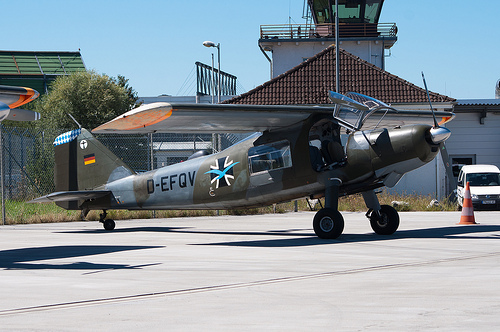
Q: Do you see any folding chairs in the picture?
A: No, there are no folding chairs.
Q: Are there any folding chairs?
A: No, there are no folding chairs.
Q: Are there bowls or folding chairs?
A: No, there are no folding chairs or bowls.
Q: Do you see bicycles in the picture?
A: No, there are no bicycles.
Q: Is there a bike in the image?
A: No, there are no bikes.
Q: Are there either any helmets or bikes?
A: No, there are no bikes or helmets.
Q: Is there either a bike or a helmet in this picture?
A: No, there are no bikes or helmets.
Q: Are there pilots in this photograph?
A: No, there are no pilots.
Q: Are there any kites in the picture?
A: No, there are no kites.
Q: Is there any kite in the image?
A: No, there are no kites.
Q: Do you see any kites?
A: No, there are no kites.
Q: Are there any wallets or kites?
A: No, there are no kites or wallets.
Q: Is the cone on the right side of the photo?
A: Yes, the cone is on the right of the image.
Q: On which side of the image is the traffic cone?
A: The traffic cone is on the right of the image.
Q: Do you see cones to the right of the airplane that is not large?
A: Yes, there is a cone to the right of the airplane.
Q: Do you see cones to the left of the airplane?
A: No, the cone is to the right of the airplane.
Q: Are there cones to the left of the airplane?
A: No, the cone is to the right of the airplane.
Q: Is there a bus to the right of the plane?
A: No, there is a cone to the right of the plane.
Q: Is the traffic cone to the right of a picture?
A: No, the traffic cone is to the right of the airplane.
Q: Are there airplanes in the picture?
A: Yes, there is an airplane.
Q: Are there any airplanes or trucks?
A: Yes, there is an airplane.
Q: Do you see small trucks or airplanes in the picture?
A: Yes, there is a small airplane.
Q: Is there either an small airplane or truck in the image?
A: Yes, there is a small airplane.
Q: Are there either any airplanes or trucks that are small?
A: Yes, the airplane is small.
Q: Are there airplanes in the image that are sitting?
A: Yes, there is an airplane that is sitting.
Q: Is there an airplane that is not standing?
A: Yes, there is an airplane that is sitting.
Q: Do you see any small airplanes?
A: Yes, there is a small airplane.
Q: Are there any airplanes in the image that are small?
A: Yes, there is an airplane that is small.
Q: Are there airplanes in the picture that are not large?
A: Yes, there is a small airplane.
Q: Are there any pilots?
A: No, there are no pilots.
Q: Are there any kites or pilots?
A: No, there are no pilots or kites.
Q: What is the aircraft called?
A: The aircraft is an airplane.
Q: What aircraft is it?
A: The aircraft is an airplane.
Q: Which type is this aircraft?
A: This is an airplane.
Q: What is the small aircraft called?
A: The aircraft is an airplane.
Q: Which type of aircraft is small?
A: The aircraft is an airplane.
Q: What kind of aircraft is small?
A: The aircraft is an airplane.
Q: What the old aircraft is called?
A: The aircraft is an airplane.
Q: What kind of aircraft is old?
A: The aircraft is an airplane.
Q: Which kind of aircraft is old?
A: The aircraft is an airplane.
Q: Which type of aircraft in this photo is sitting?
A: The aircraft is an airplane.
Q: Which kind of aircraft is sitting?
A: The aircraft is an airplane.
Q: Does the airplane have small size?
A: Yes, the airplane is small.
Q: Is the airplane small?
A: Yes, the airplane is small.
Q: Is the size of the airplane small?
A: Yes, the airplane is small.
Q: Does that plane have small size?
A: Yes, the plane is small.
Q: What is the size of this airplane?
A: The airplane is small.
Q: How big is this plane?
A: The plane is small.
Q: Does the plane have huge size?
A: No, the plane is small.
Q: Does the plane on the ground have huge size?
A: No, the airplane is small.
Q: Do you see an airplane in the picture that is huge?
A: No, there is an airplane but it is small.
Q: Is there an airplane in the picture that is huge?
A: No, there is an airplane but it is small.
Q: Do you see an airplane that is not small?
A: No, there is an airplane but it is small.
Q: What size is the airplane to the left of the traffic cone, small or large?
A: The airplane is small.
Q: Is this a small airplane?
A: Yes, this is a small airplane.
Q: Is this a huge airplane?
A: No, this is a small airplane.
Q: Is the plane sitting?
A: Yes, the plane is sitting.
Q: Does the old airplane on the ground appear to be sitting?
A: Yes, the plane is sitting.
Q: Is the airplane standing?
A: No, the airplane is sitting.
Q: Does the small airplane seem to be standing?
A: No, the airplane is sitting.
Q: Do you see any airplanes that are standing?
A: No, there is an airplane but it is sitting.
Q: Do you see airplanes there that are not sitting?
A: No, there is an airplane but it is sitting.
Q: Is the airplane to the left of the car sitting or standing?
A: The airplane is sitting.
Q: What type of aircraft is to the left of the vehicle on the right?
A: The aircraft is an airplane.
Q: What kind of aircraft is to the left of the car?
A: The aircraft is an airplane.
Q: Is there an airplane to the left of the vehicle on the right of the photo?
A: Yes, there is an airplane to the left of the car.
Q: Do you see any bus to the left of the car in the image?
A: No, there is an airplane to the left of the car.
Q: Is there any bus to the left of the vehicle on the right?
A: No, there is an airplane to the left of the car.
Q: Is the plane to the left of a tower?
A: No, the plane is to the left of the car.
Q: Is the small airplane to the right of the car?
A: No, the airplane is to the left of the car.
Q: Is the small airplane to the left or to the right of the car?
A: The airplane is to the left of the car.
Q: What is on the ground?
A: The airplane is on the ground.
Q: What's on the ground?
A: The airplane is on the ground.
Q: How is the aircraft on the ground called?
A: The aircraft is an airplane.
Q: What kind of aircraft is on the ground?
A: The aircraft is an airplane.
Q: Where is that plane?
A: The plane is on the ground.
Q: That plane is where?
A: The plane is on the ground.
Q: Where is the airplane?
A: The plane is on the ground.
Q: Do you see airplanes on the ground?
A: Yes, there is an airplane on the ground.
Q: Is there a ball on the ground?
A: No, there is an airplane on the ground.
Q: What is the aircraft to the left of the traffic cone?
A: The aircraft is an airplane.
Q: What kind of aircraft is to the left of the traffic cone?
A: The aircraft is an airplane.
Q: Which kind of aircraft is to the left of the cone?
A: The aircraft is an airplane.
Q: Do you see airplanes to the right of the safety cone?
A: No, the airplane is to the left of the safety cone.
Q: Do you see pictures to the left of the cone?
A: No, there is an airplane to the left of the cone.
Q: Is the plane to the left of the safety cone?
A: Yes, the plane is to the left of the safety cone.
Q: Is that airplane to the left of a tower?
A: No, the airplane is to the left of the safety cone.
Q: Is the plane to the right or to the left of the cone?
A: The plane is to the left of the cone.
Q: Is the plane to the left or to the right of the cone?
A: The plane is to the left of the cone.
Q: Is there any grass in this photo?
A: Yes, there is grass.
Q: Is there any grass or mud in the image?
A: Yes, there is grass.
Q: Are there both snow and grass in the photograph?
A: No, there is grass but no snow.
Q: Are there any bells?
A: No, there are no bells.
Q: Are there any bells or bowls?
A: No, there are no bells or bowls.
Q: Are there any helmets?
A: No, there are no helmets.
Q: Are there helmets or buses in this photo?
A: No, there are no helmets or buses.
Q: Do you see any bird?
A: No, there are no birds.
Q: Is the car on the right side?
A: Yes, the car is on the right of the image.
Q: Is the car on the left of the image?
A: No, the car is on the right of the image.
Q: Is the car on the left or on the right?
A: The car is on the right of the image.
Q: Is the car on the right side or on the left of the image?
A: The car is on the right of the image.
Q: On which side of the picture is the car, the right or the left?
A: The car is on the right of the image.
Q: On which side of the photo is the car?
A: The car is on the right of the image.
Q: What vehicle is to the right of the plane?
A: The vehicle is a car.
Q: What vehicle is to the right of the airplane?
A: The vehicle is a car.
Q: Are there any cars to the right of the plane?
A: Yes, there is a car to the right of the plane.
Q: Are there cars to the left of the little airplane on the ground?
A: No, the car is to the right of the plane.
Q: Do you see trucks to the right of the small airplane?
A: No, there is a car to the right of the airplane.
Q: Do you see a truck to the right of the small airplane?
A: No, there is a car to the right of the airplane.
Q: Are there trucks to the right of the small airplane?
A: No, there is a car to the right of the airplane.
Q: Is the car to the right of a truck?
A: No, the car is to the right of the plane.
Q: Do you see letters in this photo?
A: Yes, there are letters.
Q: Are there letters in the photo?
A: Yes, there are letters.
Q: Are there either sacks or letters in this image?
A: Yes, there are letters.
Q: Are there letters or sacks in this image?
A: Yes, there are letters.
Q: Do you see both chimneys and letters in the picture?
A: No, there are letters but no chimneys.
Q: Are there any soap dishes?
A: No, there are no soap dishes.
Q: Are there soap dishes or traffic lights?
A: No, there are no soap dishes or traffic lights.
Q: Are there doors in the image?
A: Yes, there is a door.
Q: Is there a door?
A: Yes, there is a door.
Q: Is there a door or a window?
A: Yes, there is a door.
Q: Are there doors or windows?
A: Yes, there is a door.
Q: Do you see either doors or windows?
A: Yes, there is a door.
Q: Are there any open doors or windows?
A: Yes, there is an open door.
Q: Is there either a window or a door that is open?
A: Yes, the door is open.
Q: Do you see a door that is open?
A: Yes, there is an open door.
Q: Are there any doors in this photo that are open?
A: Yes, there is a door that is open.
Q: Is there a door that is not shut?
A: Yes, there is a open door.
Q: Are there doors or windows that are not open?
A: No, there is a door but it is open.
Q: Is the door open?
A: Yes, the door is open.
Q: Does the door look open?
A: Yes, the door is open.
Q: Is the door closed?
A: No, the door is open.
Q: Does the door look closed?
A: No, the door is open.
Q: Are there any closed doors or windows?
A: No, there is a door but it is open.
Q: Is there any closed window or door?
A: No, there is a door but it is open.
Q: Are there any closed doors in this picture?
A: No, there is a door but it is open.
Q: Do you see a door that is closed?
A: No, there is a door but it is open.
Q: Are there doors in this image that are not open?
A: No, there is a door but it is open.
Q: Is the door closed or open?
A: The door is open.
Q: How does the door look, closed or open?
A: The door is open.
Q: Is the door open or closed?
A: The door is open.